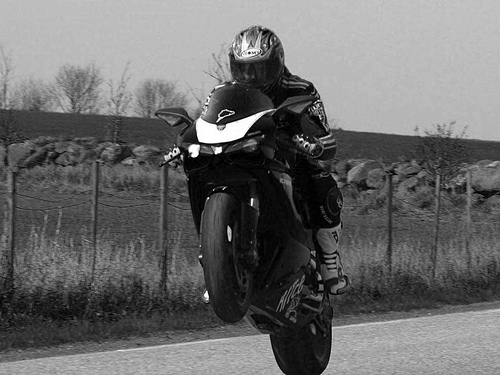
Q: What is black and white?
A: The picture.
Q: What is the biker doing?
A: Riding bike.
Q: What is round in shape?
A: Wheel.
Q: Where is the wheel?
A: On the bike.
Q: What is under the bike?
A: The road.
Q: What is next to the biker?
A: Fence.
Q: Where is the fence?
A: Near the biker.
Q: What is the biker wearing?
A: Helmet.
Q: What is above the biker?
A: The sky.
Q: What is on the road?
A: A bike.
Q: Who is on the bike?
A: A man.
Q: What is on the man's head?
A: A helmet.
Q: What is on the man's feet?
A: Sneakers.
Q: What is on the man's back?
A: A jacket.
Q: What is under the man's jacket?
A: A shirt.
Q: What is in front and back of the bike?
A: Wheels.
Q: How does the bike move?
A: Gas.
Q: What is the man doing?
A: Riding the bike.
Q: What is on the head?
A: Helmet.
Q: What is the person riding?
A: Motorcycle.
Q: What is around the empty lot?
A: Gate.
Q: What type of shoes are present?
A: Boots.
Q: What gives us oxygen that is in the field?
A: Trees.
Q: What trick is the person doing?
A: Wheelie.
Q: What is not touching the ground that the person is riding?
A: Wheel.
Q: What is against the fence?
A: Weeds.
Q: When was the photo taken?
A: Daytime.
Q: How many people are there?
A: One.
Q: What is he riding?
A: A bike.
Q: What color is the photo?
A: Black and white.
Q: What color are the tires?
A: Black.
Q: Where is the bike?
A: On the road.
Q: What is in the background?
A: Trees.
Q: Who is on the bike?
A: A biker.